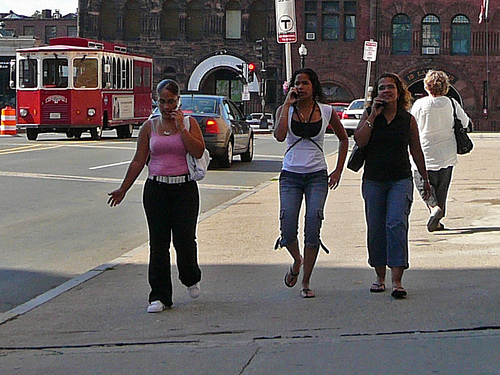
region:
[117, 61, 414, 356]
The women are on their phones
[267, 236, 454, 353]
The women are wearing sandals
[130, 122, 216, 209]
The woman's shirt is pink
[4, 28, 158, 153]
The truck is red and white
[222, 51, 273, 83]
The streetlight is red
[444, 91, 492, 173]
The woman is carrying a black purse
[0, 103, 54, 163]
The cone is orange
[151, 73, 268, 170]
The car has stopped at the streetlight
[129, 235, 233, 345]
The woman has on white shoes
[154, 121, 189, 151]
The woman has on a necklace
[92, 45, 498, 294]
Four people on the sidewalk.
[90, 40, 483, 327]
people walking down the street.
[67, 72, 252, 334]
Woman with white belt.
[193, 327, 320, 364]
Crack on the sidewalk.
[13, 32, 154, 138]
Red trolley on the road.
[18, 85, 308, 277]
Car on the road.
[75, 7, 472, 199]
Building behind the street.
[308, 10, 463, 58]
Windows on the building.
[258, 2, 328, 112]
Sign on the sidewalk.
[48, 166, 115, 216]
White stripes on the road.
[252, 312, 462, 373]
part of sidewalk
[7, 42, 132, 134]
trolley car on street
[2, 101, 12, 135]
orange and white barrel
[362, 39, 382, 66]
a sign on pole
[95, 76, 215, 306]
lady in black pants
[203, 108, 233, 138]
back light on car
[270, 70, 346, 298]
woman talking on phone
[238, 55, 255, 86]
a traffic light on red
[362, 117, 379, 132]
a bracelet on arm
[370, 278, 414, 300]
flip flops on feet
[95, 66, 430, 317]
The women walking towards the camera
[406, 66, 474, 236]
The woman walking away from the camera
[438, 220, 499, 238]
The shadow of the woman walking away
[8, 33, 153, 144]
The red trolley car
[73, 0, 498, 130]
The red brick building in the background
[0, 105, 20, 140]
The orange and white traffic cone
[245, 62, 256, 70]
The red street light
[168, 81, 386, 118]
The cell phones the women are holding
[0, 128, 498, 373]
The sidewalk the women are walking on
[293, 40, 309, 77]
The street light on the sidewalk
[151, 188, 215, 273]
Woman wearing black pants.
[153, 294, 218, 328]
Woman wearing white shoes.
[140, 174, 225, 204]
Woman wearing white belt.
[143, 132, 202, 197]
Woman wearing pink top.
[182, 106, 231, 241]
Woman has white bag over shoulder.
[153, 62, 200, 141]
Woman has dark hair.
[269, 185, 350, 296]
Woman wearing blue jean capris.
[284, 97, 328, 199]
Woman wearing white top.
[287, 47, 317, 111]
Woman holding cellphone up to face.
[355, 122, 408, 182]
Woman wearing black top.